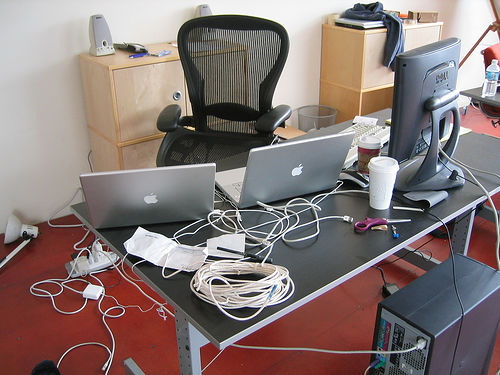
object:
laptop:
[214, 130, 359, 209]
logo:
[291, 163, 304, 176]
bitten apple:
[291, 163, 304, 176]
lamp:
[2, 213, 39, 245]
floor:
[290, 317, 344, 345]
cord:
[187, 257, 301, 322]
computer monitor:
[386, 37, 465, 168]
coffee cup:
[366, 154, 401, 211]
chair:
[154, 13, 294, 168]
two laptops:
[76, 129, 357, 231]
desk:
[468, 135, 491, 166]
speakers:
[86, 13, 117, 58]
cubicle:
[107, 60, 152, 141]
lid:
[367, 156, 400, 174]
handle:
[354, 216, 389, 231]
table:
[42, 230, 69, 260]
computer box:
[370, 251, 499, 375]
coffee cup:
[357, 136, 384, 174]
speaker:
[193, 3, 215, 18]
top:
[356, 135, 385, 150]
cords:
[249, 191, 348, 249]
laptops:
[77, 162, 217, 231]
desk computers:
[385, 36, 466, 192]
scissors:
[353, 216, 412, 232]